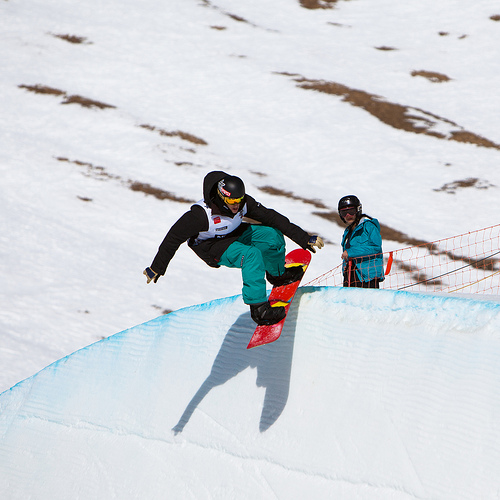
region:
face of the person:
[196, 165, 253, 217]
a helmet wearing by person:
[200, 152, 255, 221]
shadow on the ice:
[163, 353, 365, 463]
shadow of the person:
[167, 371, 317, 449]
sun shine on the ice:
[316, 374, 460, 495]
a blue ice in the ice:
[19, 351, 185, 388]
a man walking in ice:
[321, 186, 406, 304]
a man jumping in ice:
[152, 149, 362, 374]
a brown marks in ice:
[23, 59, 219, 164]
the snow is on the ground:
[25, 40, 486, 277]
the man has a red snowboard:
[239, 269, 343, 402]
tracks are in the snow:
[20, 112, 179, 376]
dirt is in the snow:
[32, 68, 342, 285]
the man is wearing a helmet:
[322, 168, 389, 214]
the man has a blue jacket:
[310, 223, 412, 298]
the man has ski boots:
[235, 278, 311, 355]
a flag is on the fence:
[362, 238, 484, 311]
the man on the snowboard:
[113, 150, 363, 354]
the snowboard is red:
[239, 244, 317, 380]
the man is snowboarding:
[122, 143, 344, 344]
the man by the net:
[330, 189, 392, 279]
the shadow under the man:
[198, 294, 323, 433]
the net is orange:
[312, 224, 498, 294]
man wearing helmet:
[201, 177, 254, 211]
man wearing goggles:
[212, 186, 247, 209]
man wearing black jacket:
[157, 187, 303, 268]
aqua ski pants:
[214, 219, 294, 307]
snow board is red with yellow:
[243, 240, 321, 346]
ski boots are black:
[217, 264, 318, 323]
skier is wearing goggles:
[219, 193, 252, 208]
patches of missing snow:
[267, 41, 487, 162]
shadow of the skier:
[199, 286, 333, 440]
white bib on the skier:
[181, 194, 281, 252]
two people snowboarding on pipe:
[101, 120, 425, 387]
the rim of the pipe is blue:
[119, 136, 428, 400]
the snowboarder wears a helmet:
[91, 114, 360, 385]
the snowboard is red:
[102, 128, 362, 391]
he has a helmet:
[320, 170, 408, 295]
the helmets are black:
[86, 148, 421, 383]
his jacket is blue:
[309, 140, 389, 282]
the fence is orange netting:
[401, 234, 466, 328]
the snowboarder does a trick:
[82, 136, 357, 371]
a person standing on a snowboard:
[141, 167, 321, 350]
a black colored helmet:
[337, 193, 363, 219]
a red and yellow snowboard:
[244, 244, 310, 348]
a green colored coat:
[338, 212, 383, 284]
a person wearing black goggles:
[337, 195, 384, 289]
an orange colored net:
[302, 227, 499, 284]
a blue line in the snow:
[4, 283, 497, 395]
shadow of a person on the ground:
[170, 285, 315, 437]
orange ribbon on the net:
[384, 250, 394, 277]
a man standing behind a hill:
[337, 191, 394, 291]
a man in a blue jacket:
[335, 191, 389, 299]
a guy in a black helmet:
[337, 197, 388, 287]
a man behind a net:
[330, 195, 385, 286]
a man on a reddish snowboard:
[145, 160, 327, 357]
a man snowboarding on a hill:
[147, 165, 329, 359]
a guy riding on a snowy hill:
[143, 164, 327, 361]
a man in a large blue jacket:
[333, 193, 390, 291]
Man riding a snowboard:
[144, 169, 327, 346]